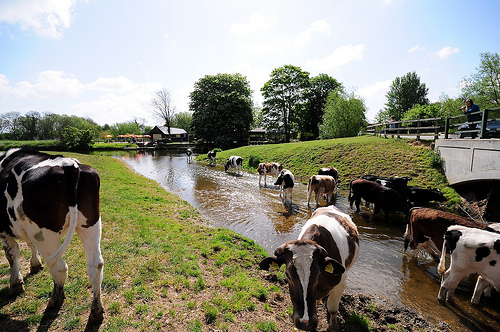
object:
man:
[459, 99, 480, 139]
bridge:
[433, 138, 499, 186]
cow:
[258, 204, 360, 330]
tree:
[384, 70, 431, 132]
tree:
[317, 87, 369, 140]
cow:
[0, 146, 107, 314]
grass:
[0, 136, 499, 332]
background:
[0, 0, 499, 331]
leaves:
[188, 73, 256, 150]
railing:
[366, 105, 500, 140]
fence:
[370, 108, 500, 139]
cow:
[224, 155, 243, 176]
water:
[106, 146, 499, 330]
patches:
[144, 235, 229, 318]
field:
[0, 130, 499, 331]